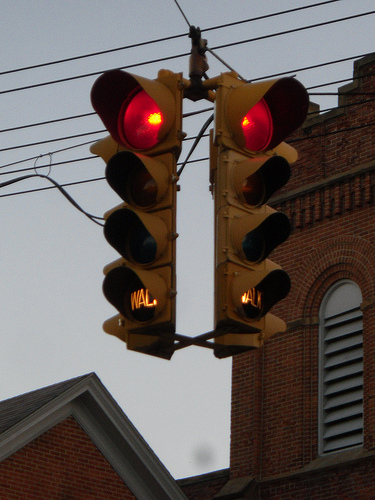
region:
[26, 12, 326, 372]
elevated traffic lights painted yellow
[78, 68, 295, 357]
red lights with walk illuminated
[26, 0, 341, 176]
rows of wires over traffic lights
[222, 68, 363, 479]
brick building with arched windows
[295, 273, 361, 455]
slats pointing downwards in window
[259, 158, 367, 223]
rows of short bricks forming pattern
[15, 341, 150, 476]
pointed roof and brick building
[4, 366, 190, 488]
white angled molding on facade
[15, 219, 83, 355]
light-gray sky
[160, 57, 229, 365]
crossed supports attached to signals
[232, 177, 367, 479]
The building is made of brick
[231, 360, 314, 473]
The brick is red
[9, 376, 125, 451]
The roof is grey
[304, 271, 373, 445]
The window is white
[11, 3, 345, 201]
There are many black lines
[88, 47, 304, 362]
The signal is yellow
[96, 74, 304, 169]
The street signal has a red light on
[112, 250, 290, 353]
The street signal has yellow words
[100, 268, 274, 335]
The words say WALK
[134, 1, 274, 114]
The signal hangs from black lines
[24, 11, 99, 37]
The sky is gray.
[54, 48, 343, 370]
A set of traffic lights.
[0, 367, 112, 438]
The roof of a building.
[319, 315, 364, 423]
Slats on a building.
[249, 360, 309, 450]
A brick building.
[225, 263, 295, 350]
The light says walk.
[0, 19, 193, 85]
Some power lines.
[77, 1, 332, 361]
The traffic lights are hanging from power lines.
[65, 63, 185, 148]
The traffic light is orange.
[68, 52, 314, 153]
Two orange traffic lights.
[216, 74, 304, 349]
Long yellow traffic light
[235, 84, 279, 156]
illuminating red traffic light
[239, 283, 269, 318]
Yellow walk light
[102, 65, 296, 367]
Set of Yellow stop lights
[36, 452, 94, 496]
Building made from brick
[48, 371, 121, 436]
high white gable roof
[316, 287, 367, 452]
Long white shutter style window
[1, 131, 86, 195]
Thin black power lines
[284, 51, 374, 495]
Tall building made of brick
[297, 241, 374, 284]
Brick designer archway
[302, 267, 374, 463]
window on a brick building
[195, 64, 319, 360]
traffic light showing red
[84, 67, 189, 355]
traffic light showing red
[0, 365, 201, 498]
roof of a brick building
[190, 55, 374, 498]
building made of brick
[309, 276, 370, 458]
large window painted white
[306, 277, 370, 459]
window with oval shaped top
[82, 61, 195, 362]
a yellow traffic light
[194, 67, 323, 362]
a yellow traffic light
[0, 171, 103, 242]
black electrical wires